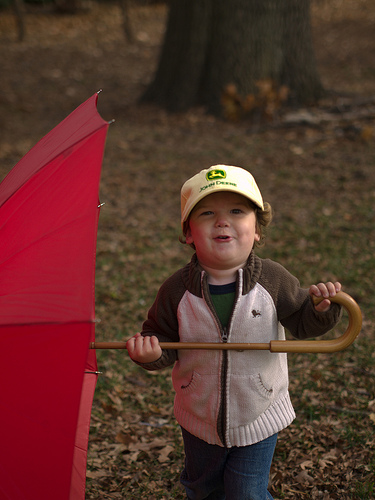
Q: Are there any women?
A: No, there are no women.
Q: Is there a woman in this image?
A: No, there are no women.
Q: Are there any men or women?
A: No, there are no women or men.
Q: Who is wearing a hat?
A: The boy is wearing a hat.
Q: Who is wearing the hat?
A: The boy is wearing a hat.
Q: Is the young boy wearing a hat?
A: Yes, the boy is wearing a hat.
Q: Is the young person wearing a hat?
A: Yes, the boy is wearing a hat.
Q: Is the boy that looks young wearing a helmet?
A: No, the boy is wearing a hat.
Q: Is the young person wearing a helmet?
A: No, the boy is wearing a hat.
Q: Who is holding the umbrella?
A: The boy is holding the umbrella.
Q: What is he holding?
A: The boy is holding the umbrella.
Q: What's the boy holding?
A: The boy is holding the umbrella.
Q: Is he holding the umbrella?
A: Yes, the boy is holding the umbrella.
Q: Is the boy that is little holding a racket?
A: No, the boy is holding the umbrella.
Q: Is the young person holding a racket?
A: No, the boy is holding the umbrella.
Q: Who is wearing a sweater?
A: The boy is wearing a sweater.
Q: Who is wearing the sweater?
A: The boy is wearing a sweater.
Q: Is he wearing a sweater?
A: Yes, the boy is wearing a sweater.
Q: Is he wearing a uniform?
A: No, the boy is wearing a sweater.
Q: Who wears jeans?
A: The boy wears jeans.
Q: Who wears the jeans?
A: The boy wears jeans.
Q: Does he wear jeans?
A: Yes, the boy wears jeans.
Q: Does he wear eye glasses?
A: No, the boy wears jeans.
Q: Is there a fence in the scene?
A: No, there are no fences.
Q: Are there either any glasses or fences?
A: No, there are no fences or glasses.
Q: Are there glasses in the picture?
A: No, there are no glasses.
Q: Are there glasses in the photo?
A: No, there are no glasses.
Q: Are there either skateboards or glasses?
A: No, there are no glasses or skateboards.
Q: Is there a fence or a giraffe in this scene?
A: No, there are no fences or giraffes.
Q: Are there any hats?
A: Yes, there is a hat.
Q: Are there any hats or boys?
A: Yes, there is a hat.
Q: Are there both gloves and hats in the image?
A: No, there is a hat but no gloves.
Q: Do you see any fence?
A: No, there are no fences.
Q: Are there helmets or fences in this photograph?
A: No, there are no fences or helmets.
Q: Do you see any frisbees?
A: No, there are no frisbees.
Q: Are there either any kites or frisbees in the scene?
A: No, there are no frisbees or kites.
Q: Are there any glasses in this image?
A: No, there are no glasses.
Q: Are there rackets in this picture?
A: No, there are no rackets.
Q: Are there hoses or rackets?
A: No, there are no rackets or hoses.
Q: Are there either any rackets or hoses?
A: No, there are no rackets or hoses.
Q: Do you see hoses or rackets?
A: No, there are no rackets or hoses.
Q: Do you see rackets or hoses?
A: No, there are no rackets or hoses.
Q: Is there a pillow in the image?
A: No, there are no pillows.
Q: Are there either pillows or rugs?
A: No, there are no pillows or rugs.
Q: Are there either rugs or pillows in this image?
A: No, there are no pillows or rugs.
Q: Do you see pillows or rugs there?
A: No, there are no pillows or rugs.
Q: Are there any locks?
A: No, there are no locks.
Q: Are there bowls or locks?
A: No, there are no locks or bowls.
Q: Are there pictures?
A: No, there are no pictures.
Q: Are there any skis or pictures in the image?
A: No, there are no pictures or skis.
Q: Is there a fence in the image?
A: No, there are no fences.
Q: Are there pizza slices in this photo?
A: No, there are no pizza slices.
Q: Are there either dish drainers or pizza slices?
A: No, there are no pizza slices or dish drainers.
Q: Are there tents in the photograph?
A: No, there are no tents.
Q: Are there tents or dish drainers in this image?
A: No, there are no tents or dish drainers.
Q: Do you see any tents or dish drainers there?
A: No, there are no tents or dish drainers.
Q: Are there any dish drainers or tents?
A: No, there are no tents or dish drainers.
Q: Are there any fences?
A: No, there are no fences.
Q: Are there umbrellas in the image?
A: Yes, there is an umbrella.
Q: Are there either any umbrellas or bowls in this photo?
A: Yes, there is an umbrella.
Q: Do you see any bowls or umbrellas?
A: Yes, there is an umbrella.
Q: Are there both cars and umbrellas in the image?
A: No, there is an umbrella but no cars.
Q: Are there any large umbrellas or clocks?
A: Yes, there is a large umbrella.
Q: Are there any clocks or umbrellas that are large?
A: Yes, the umbrella is large.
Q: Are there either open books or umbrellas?
A: Yes, there is an open umbrella.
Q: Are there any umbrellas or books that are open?
A: Yes, the umbrella is open.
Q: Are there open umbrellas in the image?
A: Yes, there is an open umbrella.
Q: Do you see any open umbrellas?
A: Yes, there is an open umbrella.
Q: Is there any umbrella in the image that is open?
A: Yes, there is an umbrella that is open.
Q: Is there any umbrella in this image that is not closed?
A: Yes, there is a open umbrella.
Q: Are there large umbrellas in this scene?
A: Yes, there is a large umbrella.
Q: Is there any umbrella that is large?
A: Yes, there is an umbrella that is large.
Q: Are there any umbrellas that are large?
A: Yes, there is an umbrella that is large.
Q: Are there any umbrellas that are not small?
A: Yes, there is a large umbrella.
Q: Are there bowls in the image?
A: No, there are no bowls.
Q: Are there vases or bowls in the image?
A: No, there are no bowls or vases.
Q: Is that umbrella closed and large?
A: No, the umbrella is large but open.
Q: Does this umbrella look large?
A: Yes, the umbrella is large.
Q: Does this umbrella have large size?
A: Yes, the umbrella is large.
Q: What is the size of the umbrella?
A: The umbrella is large.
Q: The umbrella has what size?
A: The umbrella is large.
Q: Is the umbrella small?
A: No, the umbrella is large.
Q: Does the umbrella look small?
A: No, the umbrella is large.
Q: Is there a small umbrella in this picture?
A: No, there is an umbrella but it is large.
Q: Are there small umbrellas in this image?
A: No, there is an umbrella but it is large.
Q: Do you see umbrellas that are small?
A: No, there is an umbrella but it is large.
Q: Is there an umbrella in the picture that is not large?
A: No, there is an umbrella but it is large.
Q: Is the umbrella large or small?
A: The umbrella is large.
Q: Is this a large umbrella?
A: Yes, this is a large umbrella.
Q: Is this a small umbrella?
A: No, this is a large umbrella.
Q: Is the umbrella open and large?
A: Yes, the umbrella is open and large.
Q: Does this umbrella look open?
A: Yes, the umbrella is open.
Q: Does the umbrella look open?
A: Yes, the umbrella is open.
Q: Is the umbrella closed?
A: No, the umbrella is open.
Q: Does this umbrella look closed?
A: No, the umbrella is open.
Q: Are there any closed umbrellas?
A: No, there is an umbrella but it is open.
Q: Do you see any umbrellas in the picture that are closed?
A: No, there is an umbrella but it is open.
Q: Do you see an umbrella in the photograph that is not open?
A: No, there is an umbrella but it is open.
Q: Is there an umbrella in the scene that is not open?
A: No, there is an umbrella but it is open.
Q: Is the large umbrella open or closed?
A: The umbrella is open.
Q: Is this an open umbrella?
A: Yes, this is an open umbrella.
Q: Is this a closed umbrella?
A: No, this is an open umbrella.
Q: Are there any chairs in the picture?
A: No, there are no chairs.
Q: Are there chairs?
A: No, there are no chairs.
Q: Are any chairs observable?
A: No, there are no chairs.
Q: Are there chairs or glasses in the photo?
A: No, there are no chairs or glasses.